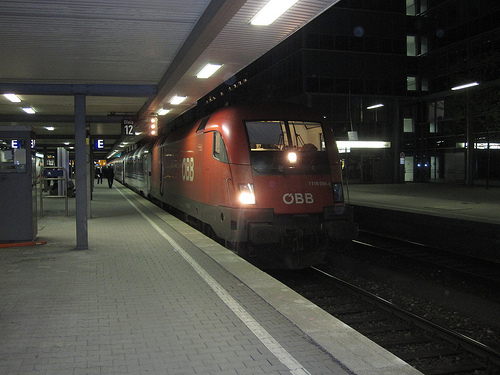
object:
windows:
[404, 74, 418, 93]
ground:
[341, 181, 499, 221]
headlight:
[329, 180, 345, 204]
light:
[235, 189, 255, 206]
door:
[156, 147, 163, 195]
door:
[142, 152, 150, 195]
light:
[96, 138, 104, 150]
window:
[286, 119, 327, 153]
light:
[246, 0, 296, 29]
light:
[153, 106, 173, 120]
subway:
[106, 95, 357, 273]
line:
[110, 183, 312, 374]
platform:
[1, 0, 421, 374]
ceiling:
[0, 0, 341, 156]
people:
[103, 163, 117, 190]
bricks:
[246, 352, 275, 361]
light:
[3, 93, 21, 106]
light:
[168, 93, 187, 108]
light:
[19, 106, 37, 115]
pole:
[68, 94, 91, 250]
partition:
[0, 134, 38, 246]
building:
[390, 0, 448, 186]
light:
[194, 62, 223, 82]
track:
[310, 240, 500, 367]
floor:
[0, 178, 422, 374]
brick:
[240, 358, 274, 370]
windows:
[241, 119, 289, 152]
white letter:
[291, 191, 306, 206]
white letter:
[303, 192, 314, 206]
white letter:
[280, 191, 296, 207]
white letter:
[186, 156, 195, 183]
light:
[43, 126, 54, 133]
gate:
[37, 164, 70, 221]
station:
[0, 0, 499, 374]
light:
[148, 117, 156, 125]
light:
[8, 138, 20, 151]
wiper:
[293, 131, 309, 149]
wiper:
[275, 130, 287, 151]